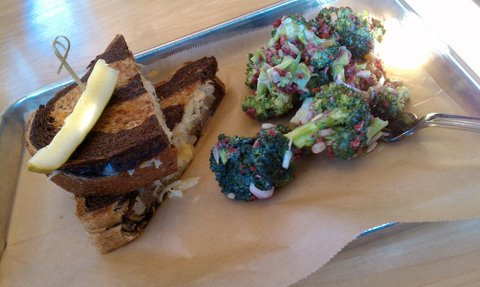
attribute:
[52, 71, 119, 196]
pickle — small, sliced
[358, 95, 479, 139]
fork — metal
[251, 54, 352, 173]
broccoli — here, green, creamy, chopped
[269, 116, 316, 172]
onions — red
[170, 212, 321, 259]
paper — wax, brown, here, parchment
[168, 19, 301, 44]
tray — metal, here, silvery, metallic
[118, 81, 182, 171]
bread — multicolored, marble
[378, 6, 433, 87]
light — relfected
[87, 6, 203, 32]
table — tan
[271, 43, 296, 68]
peppers — red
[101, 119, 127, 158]
cake — here, brown, sliced, pieced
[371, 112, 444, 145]
spoon — here, shiny, metallic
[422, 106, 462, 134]
steel — stainless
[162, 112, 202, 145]
sauerkraut — here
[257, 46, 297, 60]
bacon — crumbled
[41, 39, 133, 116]
toothpick — holding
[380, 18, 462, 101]
cream — here